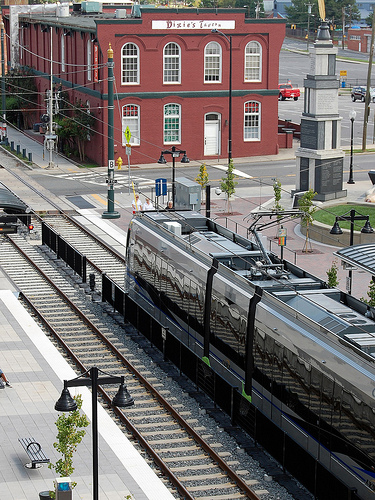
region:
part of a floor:
[104, 457, 131, 490]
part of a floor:
[120, 436, 144, 484]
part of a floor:
[83, 412, 111, 462]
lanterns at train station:
[49, 360, 134, 498]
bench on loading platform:
[13, 428, 46, 463]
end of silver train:
[114, 201, 370, 431]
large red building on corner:
[22, 11, 286, 158]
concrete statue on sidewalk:
[296, 13, 355, 203]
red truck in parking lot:
[277, 79, 299, 102]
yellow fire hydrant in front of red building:
[115, 155, 126, 170]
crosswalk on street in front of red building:
[65, 158, 154, 190]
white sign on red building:
[147, 15, 238, 32]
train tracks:
[18, 238, 115, 345]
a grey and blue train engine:
[123, 207, 329, 406]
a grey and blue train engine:
[250, 275, 374, 498]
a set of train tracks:
[0, 228, 258, 498]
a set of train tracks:
[0, 158, 135, 302]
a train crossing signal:
[35, 89, 67, 166]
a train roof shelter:
[337, 241, 373, 301]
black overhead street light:
[52, 370, 137, 495]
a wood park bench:
[16, 433, 48, 469]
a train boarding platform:
[0, 288, 174, 499]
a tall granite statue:
[291, 20, 348, 201]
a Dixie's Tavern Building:
[14, 2, 291, 156]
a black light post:
[52, 359, 127, 498]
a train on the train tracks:
[114, 187, 289, 407]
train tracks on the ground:
[5, 190, 107, 305]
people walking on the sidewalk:
[128, 187, 180, 208]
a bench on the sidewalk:
[14, 432, 55, 473]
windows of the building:
[118, 36, 223, 89]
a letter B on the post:
[105, 157, 117, 170]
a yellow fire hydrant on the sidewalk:
[114, 155, 123, 171]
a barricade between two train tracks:
[48, 227, 106, 297]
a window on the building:
[118, 99, 146, 150]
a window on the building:
[153, 102, 186, 153]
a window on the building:
[193, 107, 221, 169]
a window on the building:
[234, 93, 269, 159]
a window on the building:
[113, 37, 139, 97]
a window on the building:
[159, 35, 183, 90]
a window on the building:
[201, 42, 226, 93]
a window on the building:
[238, 38, 266, 89]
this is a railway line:
[21, 265, 206, 486]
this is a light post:
[33, 362, 139, 498]